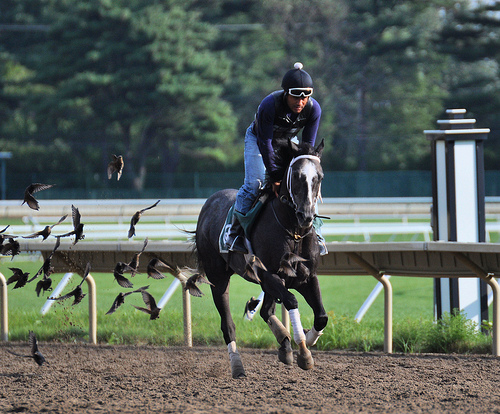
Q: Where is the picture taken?
A: At a race track.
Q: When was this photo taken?
A: During daylight.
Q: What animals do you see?
A: Horse and birds.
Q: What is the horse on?
A: Dirt.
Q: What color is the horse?
A: Black.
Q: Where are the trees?
A: Behind the race track.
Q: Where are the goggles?
A: On the riders head.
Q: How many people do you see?
A: 1.